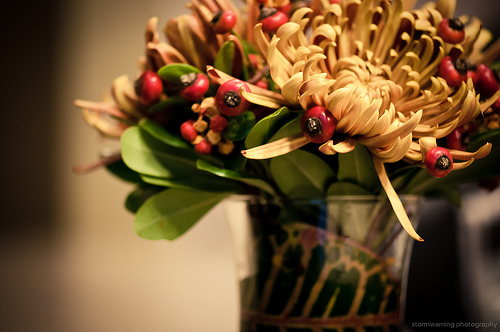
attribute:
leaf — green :
[137, 196, 217, 238]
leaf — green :
[121, 131, 190, 175]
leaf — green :
[136, 111, 192, 147]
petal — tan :
[280, 23, 294, 64]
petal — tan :
[247, 24, 270, 55]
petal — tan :
[261, 35, 281, 75]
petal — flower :
[370, 170, 425, 240]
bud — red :
[302, 105, 333, 141]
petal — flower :
[240, 134, 303, 159]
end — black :
[221, 91, 238, 108]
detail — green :
[250, 228, 397, 315]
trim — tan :
[303, 252, 331, 318]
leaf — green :
[132, 193, 220, 238]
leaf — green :
[195, 150, 272, 197]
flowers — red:
[179, 70, 259, 170]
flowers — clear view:
[107, 20, 464, 216]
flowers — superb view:
[110, 25, 465, 194]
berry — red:
[301, 105, 352, 145]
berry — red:
[413, 135, 453, 177]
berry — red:
[432, 55, 480, 85]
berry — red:
[456, 48, 496, 110]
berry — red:
[431, 11, 471, 54]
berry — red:
[240, 3, 294, 49]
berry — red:
[200, 12, 250, 32]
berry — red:
[118, 63, 181, 114]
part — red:
[210, 72, 262, 139]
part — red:
[115, 61, 181, 114]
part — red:
[170, 70, 218, 112]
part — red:
[192, 7, 249, 47]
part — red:
[419, 140, 461, 190]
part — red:
[431, 47, 469, 85]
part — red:
[429, 14, 478, 49]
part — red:
[461, 50, 493, 95]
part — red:
[457, 61, 480, 88]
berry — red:
[419, 135, 465, 181]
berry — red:
[301, 108, 335, 154]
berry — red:
[423, 45, 480, 94]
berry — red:
[472, 60, 484, 94]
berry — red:
[430, 14, 469, 49]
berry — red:
[250, 5, 291, 34]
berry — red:
[206, 6, 238, 41]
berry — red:
[131, 67, 164, 108]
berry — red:
[169, 69, 212, 102]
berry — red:
[204, 78, 249, 122]